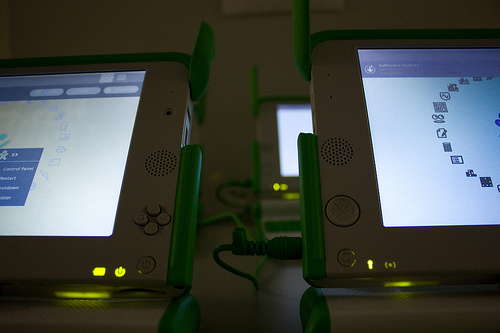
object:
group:
[132, 201, 171, 235]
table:
[188, 166, 318, 333]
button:
[112, 265, 127, 279]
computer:
[288, 0, 500, 332]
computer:
[0, 19, 223, 332]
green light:
[91, 266, 107, 278]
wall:
[0, 1, 497, 225]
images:
[447, 154, 466, 166]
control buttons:
[144, 219, 161, 235]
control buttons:
[154, 212, 170, 227]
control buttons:
[146, 201, 162, 217]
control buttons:
[133, 211, 152, 227]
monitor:
[0, 17, 222, 296]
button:
[381, 260, 397, 271]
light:
[365, 258, 376, 271]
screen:
[1, 70, 150, 238]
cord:
[210, 241, 260, 294]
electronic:
[246, 61, 316, 242]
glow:
[384, 280, 411, 289]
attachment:
[294, 131, 327, 281]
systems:
[354, 48, 497, 229]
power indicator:
[113, 265, 128, 278]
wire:
[199, 209, 254, 242]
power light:
[384, 260, 398, 269]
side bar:
[295, 130, 327, 285]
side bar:
[291, 0, 316, 87]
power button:
[135, 254, 158, 275]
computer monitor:
[290, 0, 500, 289]